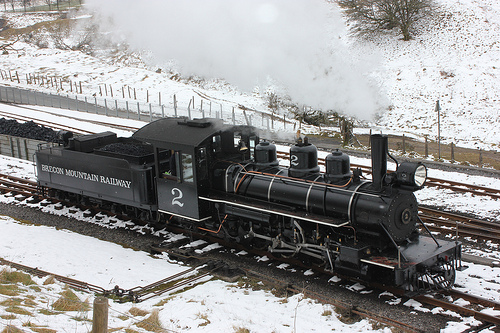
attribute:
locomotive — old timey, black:
[36, 114, 465, 291]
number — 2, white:
[168, 186, 186, 211]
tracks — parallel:
[421, 207, 499, 253]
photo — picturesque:
[0, 2, 499, 333]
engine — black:
[225, 130, 463, 287]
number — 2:
[398, 171, 410, 185]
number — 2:
[399, 208, 412, 226]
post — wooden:
[92, 296, 106, 333]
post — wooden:
[15, 70, 21, 86]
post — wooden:
[23, 0, 28, 18]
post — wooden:
[3, 0, 9, 13]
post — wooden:
[78, 81, 84, 96]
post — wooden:
[68, 79, 73, 97]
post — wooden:
[25, 72, 30, 87]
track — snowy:
[0, 173, 499, 324]